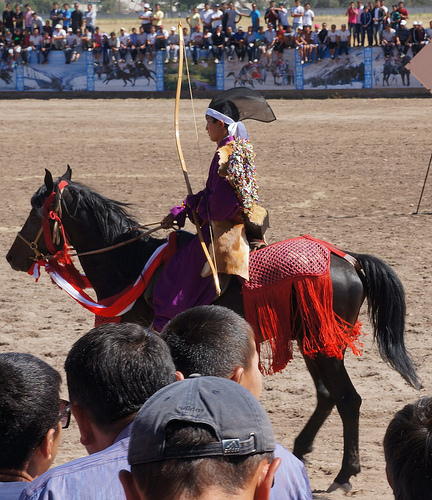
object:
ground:
[0, 97, 431, 499]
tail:
[355, 251, 424, 391]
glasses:
[38, 397, 74, 445]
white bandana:
[202, 106, 247, 143]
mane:
[64, 179, 161, 248]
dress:
[184, 134, 271, 282]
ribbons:
[45, 255, 176, 323]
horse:
[5, 163, 423, 499]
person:
[160, 82, 278, 312]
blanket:
[241, 233, 367, 376]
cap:
[126, 371, 276, 467]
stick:
[171, 21, 222, 300]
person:
[0, 350, 71, 481]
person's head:
[203, 96, 241, 143]